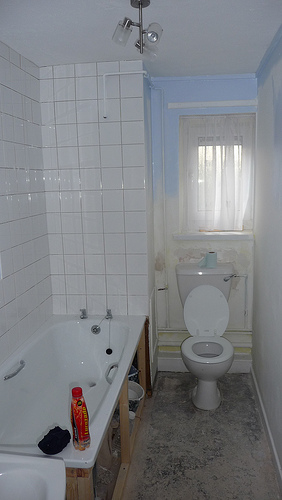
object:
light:
[110, 1, 163, 54]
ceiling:
[1, 1, 280, 76]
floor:
[121, 369, 281, 498]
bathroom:
[3, 2, 280, 499]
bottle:
[71, 389, 92, 450]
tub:
[1, 308, 150, 499]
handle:
[104, 357, 117, 385]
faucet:
[77, 308, 112, 322]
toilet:
[177, 264, 234, 411]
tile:
[1, 43, 150, 371]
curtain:
[179, 115, 254, 229]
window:
[179, 113, 254, 234]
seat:
[179, 335, 234, 365]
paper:
[199, 251, 217, 267]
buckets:
[129, 363, 143, 429]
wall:
[151, 74, 256, 371]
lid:
[182, 283, 230, 336]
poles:
[67, 317, 150, 499]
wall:
[1, 43, 150, 368]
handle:
[4, 358, 25, 382]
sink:
[1, 450, 67, 500]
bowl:
[182, 343, 233, 380]